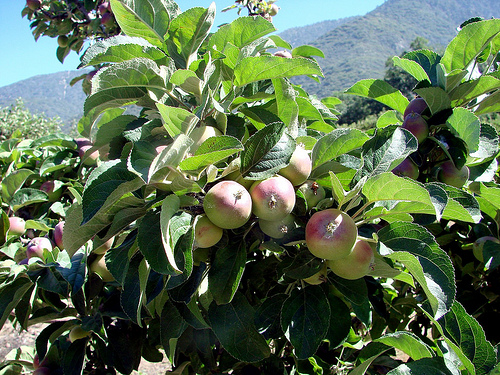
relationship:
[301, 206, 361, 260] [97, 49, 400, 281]
peach on tree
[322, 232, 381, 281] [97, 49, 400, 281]
peach on tree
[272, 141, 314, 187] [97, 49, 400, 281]
peach on tree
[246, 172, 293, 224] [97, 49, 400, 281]
peach on tree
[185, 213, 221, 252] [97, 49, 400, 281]
peach on tree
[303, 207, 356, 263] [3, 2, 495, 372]
peach on tree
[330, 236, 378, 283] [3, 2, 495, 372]
peach on tree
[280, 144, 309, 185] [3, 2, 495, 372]
peach on tree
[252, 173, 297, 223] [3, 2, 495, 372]
peach on tree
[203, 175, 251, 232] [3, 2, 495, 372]
peach on tree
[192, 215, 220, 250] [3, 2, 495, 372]
peach on tree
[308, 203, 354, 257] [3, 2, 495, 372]
peach on tree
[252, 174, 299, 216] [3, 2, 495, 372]
peach on tree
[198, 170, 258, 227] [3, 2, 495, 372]
peach on tree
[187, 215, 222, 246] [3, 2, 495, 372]
peach on tree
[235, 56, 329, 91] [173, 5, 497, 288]
leaf in sun